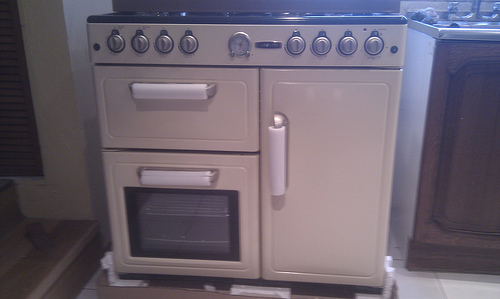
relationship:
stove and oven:
[74, 7, 406, 32] [102, 176, 244, 259]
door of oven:
[107, 156, 230, 196] [102, 176, 244, 259]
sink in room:
[426, 3, 493, 37] [0, 0, 499, 295]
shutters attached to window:
[4, 93, 46, 171] [15, 3, 60, 166]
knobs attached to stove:
[104, 28, 208, 58] [74, 7, 406, 32]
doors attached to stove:
[202, 94, 282, 269] [74, 7, 406, 32]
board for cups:
[434, 12, 498, 52] [415, 192, 472, 249]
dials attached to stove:
[318, 39, 385, 78] [74, 7, 406, 32]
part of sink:
[429, 28, 446, 43] [426, 3, 493, 37]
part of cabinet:
[289, 109, 314, 130] [269, 91, 393, 226]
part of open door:
[289, 109, 314, 130] [440, 203, 479, 258]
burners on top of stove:
[295, 9, 388, 19] [74, 7, 406, 32]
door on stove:
[107, 156, 230, 196] [74, 7, 406, 32]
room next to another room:
[84, 84, 443, 294] [2, 180, 42, 232]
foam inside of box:
[226, 287, 290, 294] [238, 289, 381, 294]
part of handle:
[289, 109, 314, 130] [118, 68, 223, 124]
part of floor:
[429, 28, 446, 43] [396, 272, 465, 290]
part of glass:
[429, 28, 446, 43] [207, 230, 224, 241]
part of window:
[429, 28, 446, 43] [15, 3, 60, 166]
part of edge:
[429, 28, 446, 43] [382, 15, 392, 26]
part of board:
[429, 28, 446, 43] [434, 12, 498, 52]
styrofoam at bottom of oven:
[49, 238, 296, 294] [102, 176, 244, 259]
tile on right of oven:
[405, 271, 449, 287] [102, 176, 244, 259]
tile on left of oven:
[405, 271, 449, 287] [102, 176, 244, 259]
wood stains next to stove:
[400, 87, 473, 154] [74, 7, 406, 32]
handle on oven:
[118, 68, 223, 124] [102, 176, 244, 259]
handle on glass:
[118, 68, 223, 124] [207, 230, 224, 241]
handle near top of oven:
[118, 68, 223, 124] [102, 176, 244, 259]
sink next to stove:
[426, 3, 493, 37] [74, 7, 406, 32]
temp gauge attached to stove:
[234, 27, 264, 61] [74, 7, 406, 32]